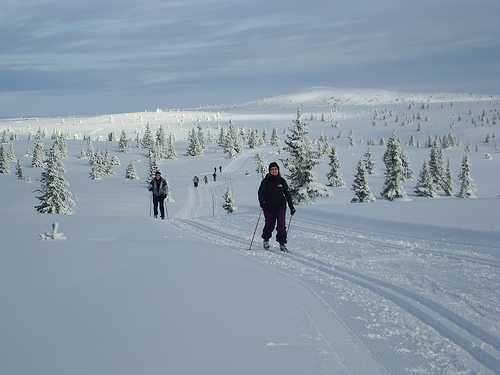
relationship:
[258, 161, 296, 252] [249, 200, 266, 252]
woman holding ski pole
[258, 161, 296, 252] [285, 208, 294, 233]
woman holding ski pole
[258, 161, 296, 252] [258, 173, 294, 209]
woman wears jacket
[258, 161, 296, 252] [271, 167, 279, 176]
woman has face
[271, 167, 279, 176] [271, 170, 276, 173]
face has smile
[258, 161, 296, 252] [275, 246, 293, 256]
woman wearing ski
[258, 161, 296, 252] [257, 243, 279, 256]
woman wearing ski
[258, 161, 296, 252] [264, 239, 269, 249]
woman wearing boot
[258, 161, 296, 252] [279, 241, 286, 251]
woman wearing boot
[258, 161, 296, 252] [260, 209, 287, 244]
woman wearing pants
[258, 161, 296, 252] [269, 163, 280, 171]
woman wearing hat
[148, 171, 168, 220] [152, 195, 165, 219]
man wearing pants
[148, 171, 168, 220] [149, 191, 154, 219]
man holding ski pole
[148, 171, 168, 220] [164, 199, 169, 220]
man holding ski pole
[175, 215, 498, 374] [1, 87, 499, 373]
ski track in snow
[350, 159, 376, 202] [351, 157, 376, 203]
snow covers tree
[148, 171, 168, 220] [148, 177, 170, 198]
man wearing jacket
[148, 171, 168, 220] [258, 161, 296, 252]
man behind woman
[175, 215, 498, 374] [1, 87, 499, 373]
ski track on snow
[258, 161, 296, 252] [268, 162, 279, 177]
woman has head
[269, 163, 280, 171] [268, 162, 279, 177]
hat covering head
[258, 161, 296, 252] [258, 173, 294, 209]
woman wearing jacket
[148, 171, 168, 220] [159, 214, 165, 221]
man wearing boot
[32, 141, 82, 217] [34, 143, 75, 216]
snow covering tree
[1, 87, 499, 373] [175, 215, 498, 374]
snow has ski track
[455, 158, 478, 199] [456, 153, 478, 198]
snow covers tree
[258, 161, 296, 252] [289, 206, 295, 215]
woman has hand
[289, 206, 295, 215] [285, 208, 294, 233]
hand holding ski pole